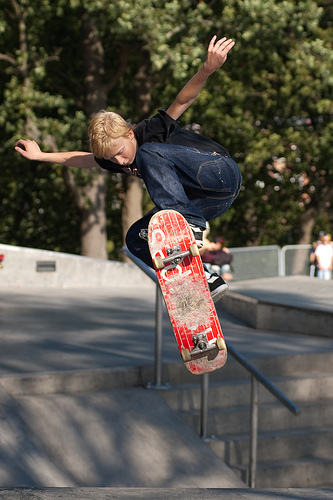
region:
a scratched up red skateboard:
[146, 209, 226, 374]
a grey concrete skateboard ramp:
[0, 384, 250, 492]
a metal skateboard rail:
[197, 374, 301, 489]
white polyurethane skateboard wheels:
[215, 336, 225, 350]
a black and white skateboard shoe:
[206, 271, 228, 300]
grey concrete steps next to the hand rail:
[259, 351, 332, 489]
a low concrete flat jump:
[226, 277, 329, 336]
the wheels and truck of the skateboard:
[181, 333, 225, 362]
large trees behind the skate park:
[244, 0, 313, 251]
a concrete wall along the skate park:
[0, 240, 122, 300]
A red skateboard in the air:
[149, 207, 229, 373]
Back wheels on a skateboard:
[181, 339, 227, 359]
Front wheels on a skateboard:
[155, 244, 198, 263]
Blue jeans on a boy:
[142, 140, 240, 228]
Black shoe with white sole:
[208, 273, 226, 297]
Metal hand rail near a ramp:
[127, 244, 299, 420]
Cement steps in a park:
[165, 365, 331, 482]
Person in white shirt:
[317, 236, 331, 282]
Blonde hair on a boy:
[90, 111, 124, 154]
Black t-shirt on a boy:
[128, 113, 230, 152]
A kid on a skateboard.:
[14, 32, 243, 374]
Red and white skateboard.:
[147, 209, 228, 375]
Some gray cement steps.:
[160, 345, 332, 488]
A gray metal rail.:
[199, 339, 299, 486]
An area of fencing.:
[228, 243, 312, 281]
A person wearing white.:
[314, 233, 332, 279]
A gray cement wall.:
[0, 244, 158, 287]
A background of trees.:
[0, 0, 332, 263]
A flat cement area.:
[0, 285, 156, 378]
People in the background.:
[198, 235, 233, 282]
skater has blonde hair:
[5, 28, 252, 306]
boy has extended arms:
[4, 16, 272, 310]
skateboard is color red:
[141, 200, 227, 379]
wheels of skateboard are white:
[150, 234, 227, 366]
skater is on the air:
[7, 19, 271, 397]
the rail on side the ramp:
[116, 239, 305, 492]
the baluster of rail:
[243, 374, 267, 491]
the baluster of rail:
[149, 282, 168, 394]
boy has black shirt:
[5, 26, 275, 381]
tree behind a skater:
[9, 12, 322, 268]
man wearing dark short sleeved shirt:
[78, 98, 228, 182]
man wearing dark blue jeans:
[88, 96, 241, 220]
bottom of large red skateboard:
[143, 205, 227, 374]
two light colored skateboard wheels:
[171, 339, 229, 363]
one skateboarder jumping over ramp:
[14, 27, 254, 492]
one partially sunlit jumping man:
[13, 31, 244, 219]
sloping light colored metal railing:
[232, 348, 302, 488]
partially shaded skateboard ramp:
[0, 372, 234, 492]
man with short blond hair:
[89, 109, 146, 167]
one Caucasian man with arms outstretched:
[13, 19, 236, 167]